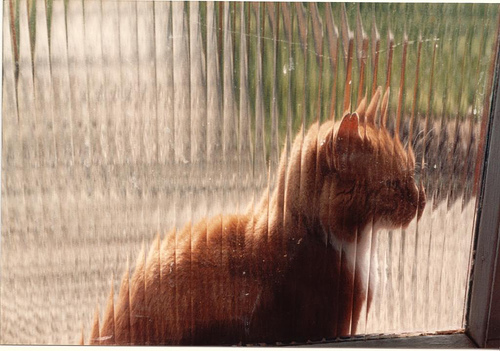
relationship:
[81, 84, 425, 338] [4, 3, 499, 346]
cat behind window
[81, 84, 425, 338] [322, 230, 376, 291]
cat partially white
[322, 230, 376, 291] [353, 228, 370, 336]
white on front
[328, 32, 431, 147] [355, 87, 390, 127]
reflection shows ears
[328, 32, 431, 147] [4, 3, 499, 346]
reflection from window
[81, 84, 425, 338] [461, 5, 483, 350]
cat looking left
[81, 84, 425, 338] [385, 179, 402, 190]
cat has eyes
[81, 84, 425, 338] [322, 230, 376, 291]
cat has white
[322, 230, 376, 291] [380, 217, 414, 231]
white under chin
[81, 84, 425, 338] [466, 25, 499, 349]
cat facing door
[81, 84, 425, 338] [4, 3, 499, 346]
cat against window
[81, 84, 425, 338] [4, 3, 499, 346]
cat outside of a window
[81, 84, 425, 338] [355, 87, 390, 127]
cat has ears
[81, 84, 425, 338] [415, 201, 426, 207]
cat has nose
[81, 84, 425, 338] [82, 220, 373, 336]
cat has body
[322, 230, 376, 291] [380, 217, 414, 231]
patch under chin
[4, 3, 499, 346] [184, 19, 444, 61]
window has scratch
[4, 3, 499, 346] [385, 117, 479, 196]
window has dirt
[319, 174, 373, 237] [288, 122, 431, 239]
fur on side of head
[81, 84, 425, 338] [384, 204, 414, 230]
cat has whiskers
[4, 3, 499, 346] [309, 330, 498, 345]
window has trim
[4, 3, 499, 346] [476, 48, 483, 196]
window has stain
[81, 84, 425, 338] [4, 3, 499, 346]
cat on or side window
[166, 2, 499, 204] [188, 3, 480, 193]
yard has grass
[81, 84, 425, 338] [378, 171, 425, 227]
cat has face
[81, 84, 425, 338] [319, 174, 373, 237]
cat has fur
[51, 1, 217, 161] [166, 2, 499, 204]
sidewalk next to yard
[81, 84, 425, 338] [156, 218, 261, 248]
cat has back